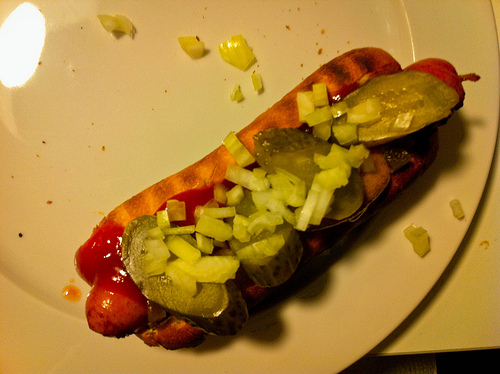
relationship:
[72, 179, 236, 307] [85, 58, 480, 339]
ketchup on hot dog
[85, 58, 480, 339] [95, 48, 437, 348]
hot dog on bun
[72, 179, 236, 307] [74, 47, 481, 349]
ketchup over a hot dog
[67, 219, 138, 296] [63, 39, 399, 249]
ketchup on bun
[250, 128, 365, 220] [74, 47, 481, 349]
jalepeno on hot dog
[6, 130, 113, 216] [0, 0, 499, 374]
brumbs on dish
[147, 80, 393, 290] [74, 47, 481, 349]
diced onion on hot dog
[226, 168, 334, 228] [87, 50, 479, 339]
onion on hotdog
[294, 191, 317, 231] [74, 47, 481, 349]
onion on hot dog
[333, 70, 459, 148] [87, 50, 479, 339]
jalepeno on a hotdog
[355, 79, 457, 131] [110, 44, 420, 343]
jalepeno on hot dog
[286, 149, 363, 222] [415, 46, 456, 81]
jalepeno on hotdog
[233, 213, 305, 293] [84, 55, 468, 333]
jalapeno on hot dog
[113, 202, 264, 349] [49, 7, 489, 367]
jalapeno on hot dog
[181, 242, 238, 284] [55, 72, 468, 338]
onion on hot dog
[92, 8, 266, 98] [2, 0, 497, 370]
onions are over dish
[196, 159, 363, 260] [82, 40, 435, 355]
onion are over hot dog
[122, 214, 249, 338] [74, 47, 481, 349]
jalapeno are over hot dog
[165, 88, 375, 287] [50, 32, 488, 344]
onions are over hot dog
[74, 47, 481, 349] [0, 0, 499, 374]
hot dog on dish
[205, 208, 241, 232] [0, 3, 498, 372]
onion on hot dog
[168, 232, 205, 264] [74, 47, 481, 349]
onion on hot dog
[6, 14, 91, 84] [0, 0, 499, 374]
light reflected on dish